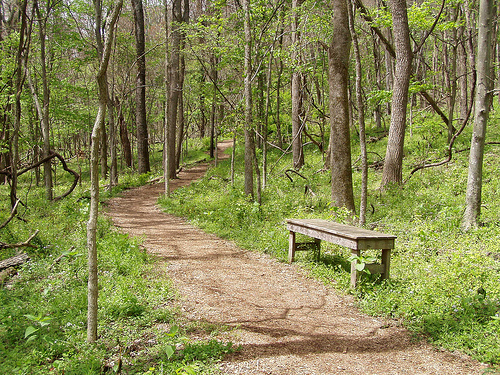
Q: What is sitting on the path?
A: A bench.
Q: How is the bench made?
A: Of wood.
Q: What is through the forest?
A: A dirt path.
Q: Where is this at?
A: Forest.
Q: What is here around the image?
A: Trees.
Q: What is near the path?
A: Bench.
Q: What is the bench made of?
A: Wood.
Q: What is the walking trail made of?
A: Dirt.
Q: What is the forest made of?
A: Wood.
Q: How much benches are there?
A: One.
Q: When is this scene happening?
A: During the day time.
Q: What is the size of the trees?
A: Thin.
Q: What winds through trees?
A: Dirt path.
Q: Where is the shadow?
A: On path.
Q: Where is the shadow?
A: The ground.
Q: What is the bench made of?
A: Wood.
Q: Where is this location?
A: Forest.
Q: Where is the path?
A: Between the forest.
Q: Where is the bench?
A: Forest.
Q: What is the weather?
A: Sun shining.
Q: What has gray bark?
A: The tree.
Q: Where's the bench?
A: Next to path.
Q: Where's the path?
A: In woods.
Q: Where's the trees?
A: In woods.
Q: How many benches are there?
A: One.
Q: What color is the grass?
A: Green.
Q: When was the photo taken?
A: Daytime.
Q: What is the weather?
A: Sunny.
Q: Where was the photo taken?
A: A forest.